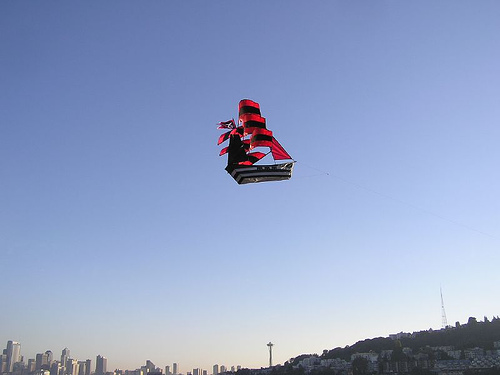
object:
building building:
[0, 339, 253, 375]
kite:
[216, 99, 296, 185]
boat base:
[223, 163, 293, 184]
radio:
[438, 287, 446, 334]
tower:
[440, 289, 448, 331]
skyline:
[0, 337, 285, 375]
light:
[266, 341, 272, 367]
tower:
[266, 342, 273, 367]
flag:
[217, 118, 236, 129]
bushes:
[428, 329, 480, 346]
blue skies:
[0, 0, 497, 375]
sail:
[269, 136, 296, 165]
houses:
[312, 315, 493, 374]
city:
[1, 340, 242, 375]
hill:
[294, 316, 500, 375]